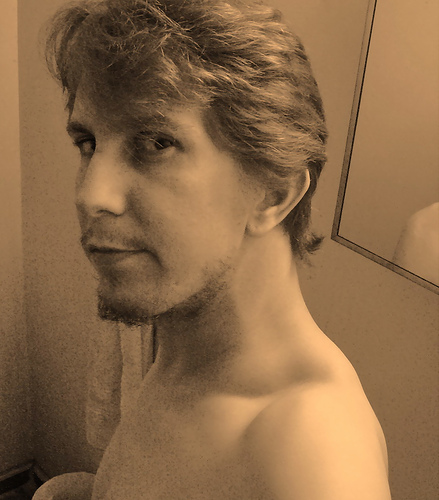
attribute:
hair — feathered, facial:
[68, 270, 202, 338]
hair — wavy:
[10, 16, 290, 119]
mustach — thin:
[55, 232, 164, 253]